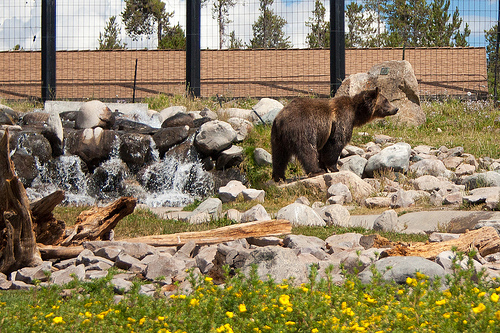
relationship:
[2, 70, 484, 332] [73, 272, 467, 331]
field has flower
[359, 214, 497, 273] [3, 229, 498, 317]
log lying among rocks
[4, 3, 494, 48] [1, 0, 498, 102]
sky outside cage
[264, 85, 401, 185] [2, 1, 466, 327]
bear in enclosure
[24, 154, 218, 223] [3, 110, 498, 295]
waterfall gushing from rock design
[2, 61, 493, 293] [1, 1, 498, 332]
rocks in cage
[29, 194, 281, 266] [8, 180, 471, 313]
log laying amongst rocks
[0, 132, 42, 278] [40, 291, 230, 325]
tree stump beyond flowers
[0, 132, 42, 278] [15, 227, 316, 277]
tree stump next to rocks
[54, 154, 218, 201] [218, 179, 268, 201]
waterfall contained by rock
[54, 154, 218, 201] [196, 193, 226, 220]
waterfall contained by rock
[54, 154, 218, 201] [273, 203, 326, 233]
waterfall contained by rock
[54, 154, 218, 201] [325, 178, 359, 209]
waterfall contained by rock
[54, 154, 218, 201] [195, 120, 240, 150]
waterfall contained by rock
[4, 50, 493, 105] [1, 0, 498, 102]
wall outside cage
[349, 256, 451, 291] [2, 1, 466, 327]
rock in enclosure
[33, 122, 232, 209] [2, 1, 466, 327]
rock in enclosure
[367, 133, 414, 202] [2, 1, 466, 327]
snowrock in enclosure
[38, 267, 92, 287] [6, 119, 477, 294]
large rock in enclosure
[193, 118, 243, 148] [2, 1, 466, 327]
large rock in enclosure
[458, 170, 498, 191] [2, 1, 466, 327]
rock in enclosure